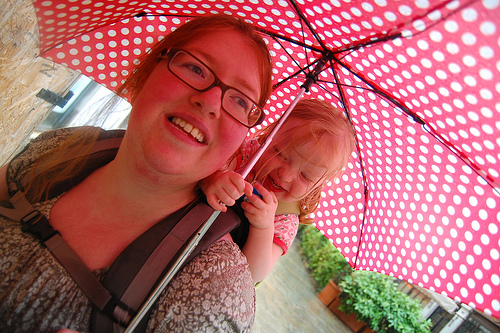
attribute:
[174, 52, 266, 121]
eyes — black, dark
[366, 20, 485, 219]
umbrella — polka dotted, red, white, polka dot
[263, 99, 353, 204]
little girl — smiling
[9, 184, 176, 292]
straps — brown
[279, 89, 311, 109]
pole — silver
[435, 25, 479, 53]
polka dots — white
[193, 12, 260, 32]
hair — red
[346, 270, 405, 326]
plants — green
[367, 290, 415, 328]
plant — potted, green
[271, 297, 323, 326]
sidewalk — brick paved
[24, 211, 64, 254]
harness — black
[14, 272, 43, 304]
blouse — brown, white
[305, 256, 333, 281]
hedge — green, trimmed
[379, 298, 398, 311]
leaves — green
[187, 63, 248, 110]
eyes — blue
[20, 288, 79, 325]
shirt — printed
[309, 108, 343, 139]
hair — blonde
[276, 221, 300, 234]
shirt — pink